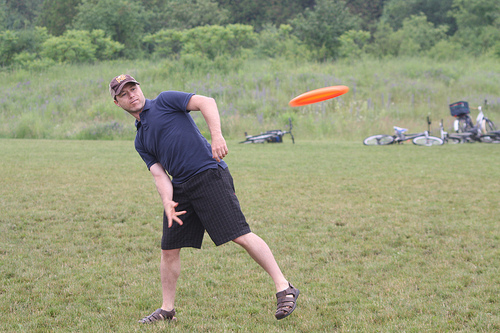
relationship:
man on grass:
[106, 72, 300, 323] [0, 136, 497, 331]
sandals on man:
[259, 283, 300, 317] [84, 61, 300, 324]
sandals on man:
[137, 300, 195, 326] [84, 61, 300, 324]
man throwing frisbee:
[106, 72, 300, 323] [285, 79, 352, 109]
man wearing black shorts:
[106, 72, 300, 323] [159, 165, 253, 250]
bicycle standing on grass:
[450, 102, 477, 132] [435, 126, 488, 156]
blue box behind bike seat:
[448, 98, 471, 118] [445, 99, 471, 116]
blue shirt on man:
[132, 93, 214, 173] [142, 101, 223, 171]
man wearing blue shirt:
[106, 72, 300, 323] [132, 90, 227, 183]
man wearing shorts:
[106, 72, 300, 323] [160, 165, 248, 250]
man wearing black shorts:
[93, 77, 340, 324] [159, 165, 253, 250]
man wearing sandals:
[106, 72, 300, 323] [272, 283, 300, 322]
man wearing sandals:
[106, 72, 300, 323] [137, 300, 179, 326]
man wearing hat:
[106, 72, 300, 323] [111, 74, 140, 98]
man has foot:
[106, 72, 300, 323] [275, 285, 298, 320]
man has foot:
[106, 72, 300, 323] [133, 305, 183, 330]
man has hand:
[106, 72, 300, 323] [175, 67, 256, 165]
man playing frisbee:
[84, 61, 300, 324] [279, 73, 351, 115]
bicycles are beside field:
[219, 103, 499, 162] [1, 136, 498, 331]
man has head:
[106, 72, 300, 323] [108, 72, 147, 111]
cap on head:
[108, 68, 143, 95] [108, 72, 147, 111]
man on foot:
[106, 72, 300, 323] [140, 303, 180, 331]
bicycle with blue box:
[444, 102, 499, 142] [448, 98, 471, 118]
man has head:
[106, 72, 300, 323] [106, 72, 149, 117]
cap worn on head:
[108, 68, 143, 95] [106, 72, 149, 117]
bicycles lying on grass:
[239, 118, 299, 145] [0, 136, 497, 331]